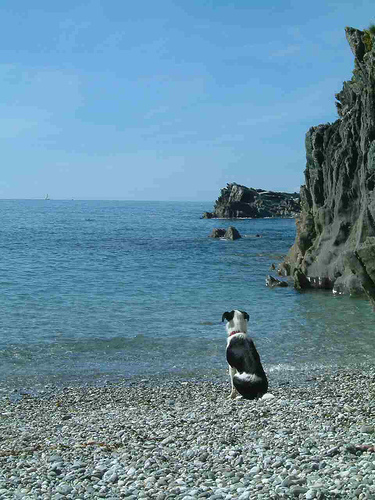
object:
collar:
[229, 331, 244, 334]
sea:
[0, 197, 373, 382]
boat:
[40, 193, 48, 199]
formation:
[198, 180, 298, 220]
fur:
[227, 332, 257, 367]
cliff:
[275, 27, 373, 298]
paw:
[228, 388, 236, 399]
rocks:
[290, 482, 310, 494]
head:
[219, 308, 251, 333]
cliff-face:
[266, 24, 374, 297]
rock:
[208, 222, 243, 243]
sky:
[0, 0, 375, 203]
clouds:
[1, 2, 373, 204]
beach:
[0, 367, 374, 498]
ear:
[241, 309, 251, 321]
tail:
[231, 374, 269, 400]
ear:
[221, 310, 235, 320]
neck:
[224, 323, 254, 339]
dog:
[218, 305, 270, 403]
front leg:
[226, 364, 236, 397]